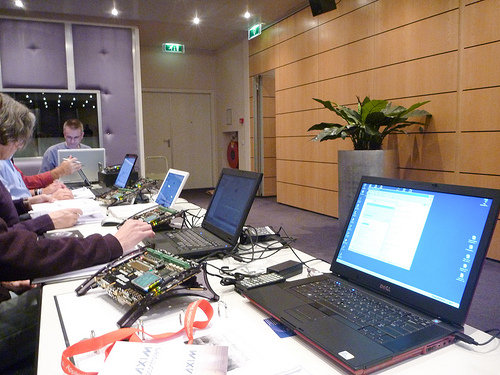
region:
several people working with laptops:
[4, 102, 497, 367]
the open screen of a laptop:
[265, 178, 497, 367]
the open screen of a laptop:
[159, 173, 267, 263]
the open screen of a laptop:
[147, 170, 196, 206]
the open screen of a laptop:
[112, 150, 146, 188]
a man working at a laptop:
[28, 111, 108, 183]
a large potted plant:
[306, 78, 432, 238]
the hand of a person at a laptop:
[104, 209, 221, 265]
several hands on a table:
[31, 150, 151, 260]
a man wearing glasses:
[55, 112, 88, 149]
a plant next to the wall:
[312, 89, 425, 146]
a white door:
[143, 93, 215, 183]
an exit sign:
[163, 41, 185, 53]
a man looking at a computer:
[43, 120, 100, 180]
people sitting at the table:
[3, 105, 70, 257]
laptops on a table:
[50, 141, 498, 363]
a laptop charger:
[269, 250, 304, 277]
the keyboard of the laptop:
[295, 267, 425, 347]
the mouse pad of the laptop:
[299, 300, 322, 320]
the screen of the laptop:
[337, 180, 499, 295]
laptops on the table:
[59, 125, 497, 372]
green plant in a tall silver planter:
[290, 78, 451, 250]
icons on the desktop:
[451, 228, 481, 288]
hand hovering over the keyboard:
[121, 214, 227, 262]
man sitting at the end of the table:
[30, 113, 130, 200]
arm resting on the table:
[26, 230, 130, 280]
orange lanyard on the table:
[58, 303, 223, 374]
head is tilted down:
[59, 117, 91, 151]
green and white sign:
[158, 38, 192, 56]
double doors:
[135, 84, 228, 191]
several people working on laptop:
[0, 94, 497, 360]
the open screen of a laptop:
[248, 175, 493, 373]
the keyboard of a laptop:
[292, 273, 438, 343]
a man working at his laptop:
[31, 106, 111, 178]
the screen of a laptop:
[343, 167, 493, 322]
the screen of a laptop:
[198, 157, 265, 239]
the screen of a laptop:
[157, 156, 188, 211]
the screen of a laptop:
[110, 145, 137, 188]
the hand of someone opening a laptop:
[24, 150, 91, 192]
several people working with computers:
[0, 81, 495, 371]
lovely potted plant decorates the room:
[300, 81, 436, 233]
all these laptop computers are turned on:
[92, 143, 497, 373]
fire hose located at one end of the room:
[218, 123, 248, 177]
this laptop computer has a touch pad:
[281, 290, 341, 331]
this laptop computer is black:
[138, 163, 268, 257]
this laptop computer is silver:
[54, 144, 112, 186]